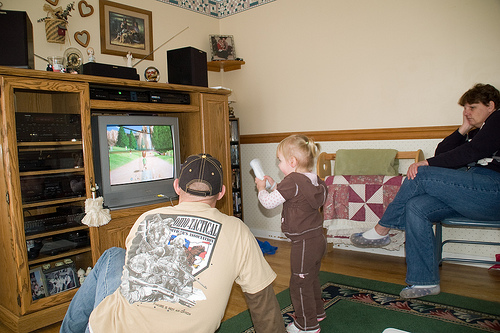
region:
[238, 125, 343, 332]
young girl playing wii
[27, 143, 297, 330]
man sitting on the floor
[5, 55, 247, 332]
wood entertainment system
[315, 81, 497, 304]
woman watching child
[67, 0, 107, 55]
two hearts hanging on the wall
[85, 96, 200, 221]
silver tv console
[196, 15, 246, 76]
wood corner shelf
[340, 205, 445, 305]
pair of grey slippers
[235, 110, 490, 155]
a wood border on the wall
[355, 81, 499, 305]
woman sitting on a green folding chair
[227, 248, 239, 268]
the shirt is brown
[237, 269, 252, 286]
the shirt is brown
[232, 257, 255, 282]
the shirt is brown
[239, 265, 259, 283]
the shirt is brown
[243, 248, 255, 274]
the shirt is brown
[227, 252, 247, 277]
the shirt is brown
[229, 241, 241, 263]
the shirt is brown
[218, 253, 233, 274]
the shirt is brown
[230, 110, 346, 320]
a little girl playing a game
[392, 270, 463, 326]
a woman wearing a slipper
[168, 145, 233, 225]
a man in a brown hat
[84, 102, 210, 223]
a small gray tv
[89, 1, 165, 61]
a brown picture on the wall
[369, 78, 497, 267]
a woman sitting in the corner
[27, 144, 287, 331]
a man sitting on the floor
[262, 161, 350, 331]
a girl wearing brown clothes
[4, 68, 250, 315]
an entertainment center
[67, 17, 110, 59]
a heart shaped frame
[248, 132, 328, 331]
Girl playing video game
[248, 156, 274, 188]
Video game controller in the girl's hands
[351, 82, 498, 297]
Woman sitting on a chair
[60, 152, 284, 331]
Man sitting on the floor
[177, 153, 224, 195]
Hat on the man's head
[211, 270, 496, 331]
Rug on the floor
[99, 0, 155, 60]
Picture on the wall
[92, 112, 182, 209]
TV on the TV stand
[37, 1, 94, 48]
Wall decorations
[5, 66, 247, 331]
Wood cabinet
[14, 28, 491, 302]
A living room scene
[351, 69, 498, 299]
The woman is sitting on a chair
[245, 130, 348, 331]
The child is holding a video game controller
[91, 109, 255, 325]
The man is watching the game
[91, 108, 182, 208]
The video game is displayed on the television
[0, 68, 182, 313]
An entertainment center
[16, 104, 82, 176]
A stereo system is on the shelf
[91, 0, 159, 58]
A framed painting is on the wall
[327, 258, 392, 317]
A rug is on the floor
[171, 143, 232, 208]
The man is wearing a ball cap